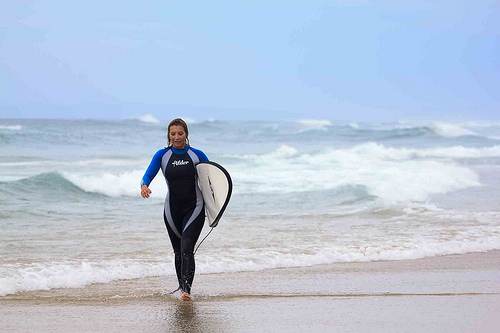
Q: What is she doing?
A: Leaving the water.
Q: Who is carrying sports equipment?
A: A woman.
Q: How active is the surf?
A: Very frothy.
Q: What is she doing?
A: Surfboarding.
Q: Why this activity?
A: It is exercise and fun.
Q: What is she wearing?
A: A wetsuit.